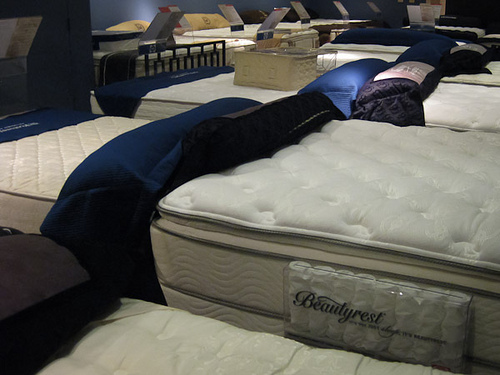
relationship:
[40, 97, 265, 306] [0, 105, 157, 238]
pillow on mattress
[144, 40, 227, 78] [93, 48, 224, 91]
headboard at end of mattress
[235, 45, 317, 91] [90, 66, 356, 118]
basket on mattress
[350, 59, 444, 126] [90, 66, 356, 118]
black pillow on mattress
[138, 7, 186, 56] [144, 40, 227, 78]
information sheets on headboard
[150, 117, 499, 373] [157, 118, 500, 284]
mattress with pillow top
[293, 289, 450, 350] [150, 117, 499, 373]
brand name of mattress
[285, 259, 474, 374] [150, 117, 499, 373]
coil samples of mattress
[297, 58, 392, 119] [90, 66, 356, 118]
blue pillow on mattress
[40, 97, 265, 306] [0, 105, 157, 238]
blue pillow on mattress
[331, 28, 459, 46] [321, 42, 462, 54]
blue pillow on mattress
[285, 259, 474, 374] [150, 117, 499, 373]
sample of inside mattress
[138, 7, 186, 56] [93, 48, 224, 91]
information sheet for mattress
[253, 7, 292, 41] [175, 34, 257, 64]
information sheet for mattress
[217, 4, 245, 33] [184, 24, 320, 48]
information sheet for mattress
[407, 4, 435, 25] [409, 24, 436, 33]
information sheet plastic holder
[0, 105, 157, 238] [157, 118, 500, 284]
mattress without pillow top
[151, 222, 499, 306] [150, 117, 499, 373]
piping around mattress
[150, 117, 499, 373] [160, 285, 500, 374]
mattress with box spring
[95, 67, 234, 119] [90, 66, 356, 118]
blue cover on mattress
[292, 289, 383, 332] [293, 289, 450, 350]
black letters spell brand name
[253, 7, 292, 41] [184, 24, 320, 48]
information sheet on end of mattress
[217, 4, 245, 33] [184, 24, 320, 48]
information sheet on end of mattress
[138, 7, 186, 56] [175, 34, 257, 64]
information sheet on end of mattress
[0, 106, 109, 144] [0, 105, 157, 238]
blankets on mattress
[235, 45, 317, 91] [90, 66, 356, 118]
white basket on mattress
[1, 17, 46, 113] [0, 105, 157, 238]
information sheet for mattress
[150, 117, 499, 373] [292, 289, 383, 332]
mattress made by beauty rest brand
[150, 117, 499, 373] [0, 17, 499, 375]
mattress in store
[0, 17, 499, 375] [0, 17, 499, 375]
mattresses for sale in store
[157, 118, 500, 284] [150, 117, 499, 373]
pillow top pads mattress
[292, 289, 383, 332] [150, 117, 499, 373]
company logo on side of mattress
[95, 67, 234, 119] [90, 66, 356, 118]
blanket on bed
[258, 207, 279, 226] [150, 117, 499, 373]
dip in bed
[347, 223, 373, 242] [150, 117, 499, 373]
dip in bed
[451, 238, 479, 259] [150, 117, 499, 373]
dip in bed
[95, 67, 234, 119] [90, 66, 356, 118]
blue blanket on mattress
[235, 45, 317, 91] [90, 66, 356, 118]
box on bed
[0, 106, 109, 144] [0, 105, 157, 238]
blankets on bed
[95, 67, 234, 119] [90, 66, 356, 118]
dark blanket on bed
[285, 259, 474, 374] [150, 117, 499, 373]
label on mattress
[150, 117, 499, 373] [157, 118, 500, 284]
mattress with quilted top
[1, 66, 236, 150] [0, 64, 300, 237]
blankets on bed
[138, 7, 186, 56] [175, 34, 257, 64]
information sheets on mattress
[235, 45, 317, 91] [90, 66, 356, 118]
wicker basket on bed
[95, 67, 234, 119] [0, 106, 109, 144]
dark blue blankets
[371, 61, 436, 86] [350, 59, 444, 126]
printed fabric on blanket